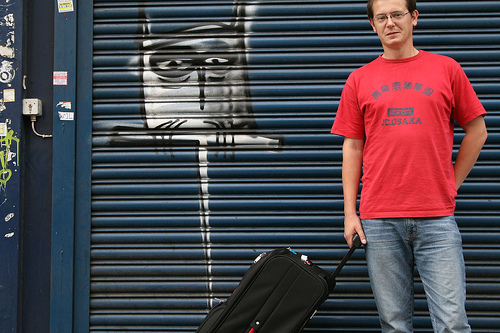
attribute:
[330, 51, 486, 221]
t-shirt — red, short sleeved, jc osaka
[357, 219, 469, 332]
jeans — faded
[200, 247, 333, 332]
suitcase — black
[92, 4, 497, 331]
garage door — blue, metal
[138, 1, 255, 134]
owl — silver, black, graffiti, white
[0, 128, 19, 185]
paint splatters — green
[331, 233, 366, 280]
handle — black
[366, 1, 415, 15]
hair — short, brown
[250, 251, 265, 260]
lock — silver